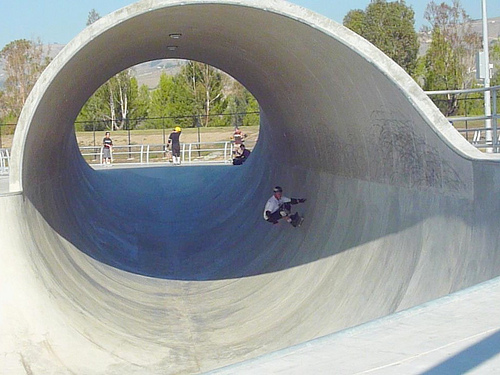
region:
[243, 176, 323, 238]
The man is skateboarding.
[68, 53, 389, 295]
Man is skateboarding in a cement structure.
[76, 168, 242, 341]
The skateboard surface is gray.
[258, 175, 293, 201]
The man is wearing a helmet.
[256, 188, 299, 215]
The mans shirt is white.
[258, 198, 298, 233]
The mans pants are black.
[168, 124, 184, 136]
The man has a yellow helmet.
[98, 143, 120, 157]
The man is wearing gray shorts.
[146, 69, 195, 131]
The tree is green.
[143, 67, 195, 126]
The tree is tall.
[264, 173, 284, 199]
The man is wearing a safety helmet.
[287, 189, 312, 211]
The man is wearing a glove.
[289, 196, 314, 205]
The glove is black.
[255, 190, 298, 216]
The man is wearing a white shirt.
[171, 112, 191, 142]
The man has a yellow helmet.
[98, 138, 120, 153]
The man's shirt is black.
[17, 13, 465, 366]
photograph taken at a skateboard park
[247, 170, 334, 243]
man on a skateboard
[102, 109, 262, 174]
people going to skateboard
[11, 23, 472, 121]
green trees in the background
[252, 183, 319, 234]
person wearing a white t-shirt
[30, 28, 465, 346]
large cement tunnel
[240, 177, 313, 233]
person wearing a safety helmet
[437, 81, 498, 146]
silver metal fencing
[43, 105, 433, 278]
shadow on cement tunnel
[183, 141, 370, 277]
the person is skateboarding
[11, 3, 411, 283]
the tunnel is circular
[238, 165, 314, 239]
the person is riding on the wall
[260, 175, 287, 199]
the helmet is dark colored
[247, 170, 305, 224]
person is wearing a white shirt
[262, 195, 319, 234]
person is wearing gloves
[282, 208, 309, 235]
the skateboard is black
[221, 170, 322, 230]
A man inside the ramp.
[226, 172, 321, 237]
A person skateboarding in the ramp.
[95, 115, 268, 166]
People standing outside of the ramp.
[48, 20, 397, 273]
The ramp is a circle.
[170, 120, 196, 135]
The helmet is yellow.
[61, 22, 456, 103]
Trees behind the fence.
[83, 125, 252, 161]
The people is standing by the fence.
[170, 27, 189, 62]
Lights on top of the ramp.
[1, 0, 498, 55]
clear blue daytime sky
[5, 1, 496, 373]
tunnel shaped skate ramp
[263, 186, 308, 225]
crouched skateboarder with extended hand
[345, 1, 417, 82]
green leaves on trees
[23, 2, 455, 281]
shadow in skate tunnel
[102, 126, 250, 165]
boys standing in front of fence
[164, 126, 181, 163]
boy in yellow hat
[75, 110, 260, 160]
poles of chain link fence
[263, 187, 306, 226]
Skateboarder inside the round concrete area.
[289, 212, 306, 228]
Black top skateboard a skater is on.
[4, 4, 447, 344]
Large rounded concrete circle to skate in.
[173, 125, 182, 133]
Yellow hat on a guys head.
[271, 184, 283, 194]
Black helmet on the skater in the round tunnels head.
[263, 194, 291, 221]
White shirt on the skater in the tunnel tube.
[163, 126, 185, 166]
Skater with yellow hat on.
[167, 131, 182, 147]
Black shirt on a person with yellow hat on.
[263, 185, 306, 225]
Skater with black helmet on and white shirt.